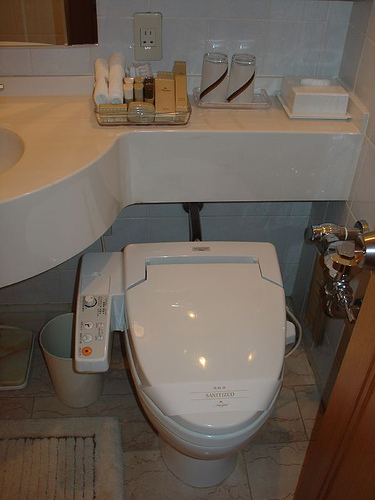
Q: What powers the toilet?
A: Electricity.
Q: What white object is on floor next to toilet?
A: Rug.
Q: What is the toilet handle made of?
A: Chrome.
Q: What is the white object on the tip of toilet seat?
A: Paper.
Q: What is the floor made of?
A: Marble.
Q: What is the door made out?
A: Wood.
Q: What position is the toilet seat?
A: Closed.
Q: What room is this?
A: Bathroom.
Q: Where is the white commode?
A: In the bathroom.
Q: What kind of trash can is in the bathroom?
A: Beige.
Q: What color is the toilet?
A: White.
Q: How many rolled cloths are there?
A: 2.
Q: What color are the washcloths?
A: White.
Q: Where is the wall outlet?
A: Near the mirror's corner.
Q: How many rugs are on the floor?
A: 1.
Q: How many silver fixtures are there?
A: 1.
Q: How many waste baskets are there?
A: 1.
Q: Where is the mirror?
A: On the wall.